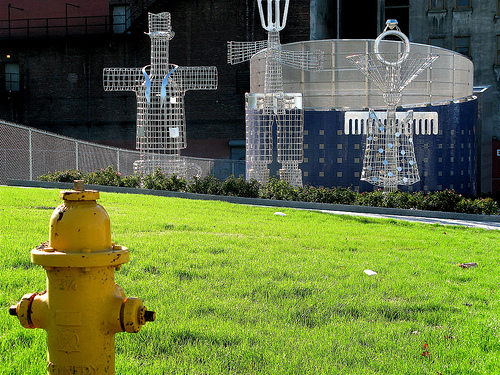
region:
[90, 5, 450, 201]
human figures made of airy metal grids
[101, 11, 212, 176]
arms out to sides with hat on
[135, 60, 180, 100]
open blue tie around neck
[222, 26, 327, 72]
scarf wrapped around neck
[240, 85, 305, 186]
cylindrical trousers above shoes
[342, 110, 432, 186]
skirt with blue dots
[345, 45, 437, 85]
arms reaching upward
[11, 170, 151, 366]
yellow fire hydrant set in grassy area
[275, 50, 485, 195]
blue wall with pattern of white squares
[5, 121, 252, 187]
curved metal fencing along side and back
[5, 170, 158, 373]
A yellow fire hydrant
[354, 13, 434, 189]
A metal wire sculpture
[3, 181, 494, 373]
A green grass lawn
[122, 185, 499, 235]
A concrete path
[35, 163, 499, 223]
Some short green shrubs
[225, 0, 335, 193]
A tall metal structure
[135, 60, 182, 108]
A curved blue piece of shiny metal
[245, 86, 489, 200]
a blue and white curved building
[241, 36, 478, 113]
A gray metal fence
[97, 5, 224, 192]
A medium sized metal sculpture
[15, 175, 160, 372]
a yellow fire hydrant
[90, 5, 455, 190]
metal sculptures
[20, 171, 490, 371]
a fire hydrant on the lawn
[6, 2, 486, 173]
sculptures in a park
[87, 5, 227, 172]
a metal sculpture of a figure with a top hat and an undone tie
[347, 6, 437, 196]
a sculpture with a large diamond ring up top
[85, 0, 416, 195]
metal wire sculptures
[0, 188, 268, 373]
a bright yellow fire hydrant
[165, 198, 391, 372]
bright green grass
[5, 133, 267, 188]
a chain link fence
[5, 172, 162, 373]
Yellow fire hydrant on grass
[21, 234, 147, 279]
bolts on yellow fire hydrant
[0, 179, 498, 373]
Green grass on a slope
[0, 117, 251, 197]
Silver chain link fence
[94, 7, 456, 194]
Metal statues in front of building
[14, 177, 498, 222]
Cement curb on side of road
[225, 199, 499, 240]
Road running down hill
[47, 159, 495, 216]
Green plants at curbside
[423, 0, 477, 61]
Windows on gray building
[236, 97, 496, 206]
Blue wall with gray squares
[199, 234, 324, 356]
field covered in green grass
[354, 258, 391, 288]
small grey rock laying in field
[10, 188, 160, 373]
yellow metal fire hydrant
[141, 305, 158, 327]
rusted brown bolt on side of hydrant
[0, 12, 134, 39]
black metal guard railing on building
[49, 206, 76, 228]
rust spot on side of fire hydrant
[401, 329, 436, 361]
small red leaves laying in grass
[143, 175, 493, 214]
row of bushes with purple blooms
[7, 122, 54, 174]
grey metal chain length fencing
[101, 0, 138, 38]
white door on side of building